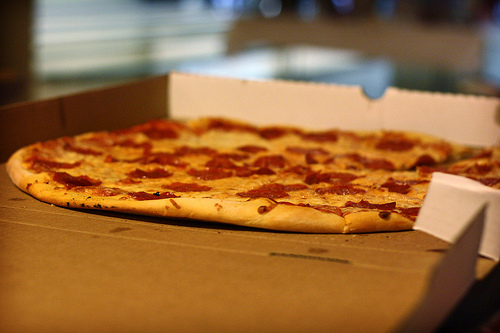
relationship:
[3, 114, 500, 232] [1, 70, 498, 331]
pizza in box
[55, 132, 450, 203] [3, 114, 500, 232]
pepperoni on pizza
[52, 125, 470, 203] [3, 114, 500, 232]
cheese on pizza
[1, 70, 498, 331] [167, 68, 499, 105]
box has a perforated top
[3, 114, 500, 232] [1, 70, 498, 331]
pizza in a box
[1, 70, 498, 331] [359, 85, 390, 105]
box has a hole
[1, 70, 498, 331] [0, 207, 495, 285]
box has a section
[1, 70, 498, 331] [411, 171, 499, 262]
box has a cardboard flap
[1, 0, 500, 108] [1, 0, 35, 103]
room has a wall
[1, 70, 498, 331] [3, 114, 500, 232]
box has a pizza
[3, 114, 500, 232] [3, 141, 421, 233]
pizza has a crust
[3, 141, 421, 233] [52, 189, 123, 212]
crust has seasoning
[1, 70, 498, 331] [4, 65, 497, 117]
box has perforated edge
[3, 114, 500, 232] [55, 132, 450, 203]
pizza has pepperoni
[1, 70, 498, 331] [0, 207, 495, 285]
box divided into section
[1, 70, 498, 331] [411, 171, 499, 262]
box has cardboard flap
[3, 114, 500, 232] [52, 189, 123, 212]
pizza has seasoning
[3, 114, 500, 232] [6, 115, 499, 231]
pizza cut into slices